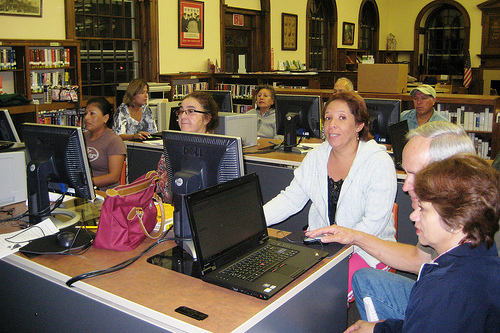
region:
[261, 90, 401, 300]
woman sitting at a table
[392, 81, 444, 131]
man sitting at a computer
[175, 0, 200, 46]
framed picture on wall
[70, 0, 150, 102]
large glass window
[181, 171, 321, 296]
black laptop on table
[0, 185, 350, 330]
long table with computers on it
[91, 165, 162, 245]
bright pink bag on table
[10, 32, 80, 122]
bookcase with many books in it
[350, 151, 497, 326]
older lady sitting at table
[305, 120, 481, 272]
older man next to lady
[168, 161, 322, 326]
the screen is off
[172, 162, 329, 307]
the computer is black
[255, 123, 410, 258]
the cloth is white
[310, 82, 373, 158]
the woman is smiling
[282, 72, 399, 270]
the woman is white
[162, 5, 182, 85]
the wall is yellow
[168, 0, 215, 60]
the picture is hanging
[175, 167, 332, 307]
the computer is off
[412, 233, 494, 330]
the shirt is dark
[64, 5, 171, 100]
the window is closed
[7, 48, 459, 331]
Computers at a library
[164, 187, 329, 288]
Black laptop computer on table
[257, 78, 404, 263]
Woman in white sitting in front of computer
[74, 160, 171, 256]
Pink purse on table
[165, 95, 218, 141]
Woman wearing glasses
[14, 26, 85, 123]
Book shelf against wall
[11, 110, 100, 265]
Back of a computer monitor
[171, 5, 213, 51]
Framed poster on library wall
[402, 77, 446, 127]
Man wearing baseball hat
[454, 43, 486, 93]
Flag in the back of a room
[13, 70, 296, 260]
women working on computers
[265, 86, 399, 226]
woman wearing a white hoodie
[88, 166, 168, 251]
pink handbag with leather trim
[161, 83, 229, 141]
woman wearing cat-eye glasses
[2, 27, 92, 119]
wood bookcase in a library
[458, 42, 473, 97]
american flag on a flag pole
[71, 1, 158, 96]
large window partially open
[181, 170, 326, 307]
black laptop computer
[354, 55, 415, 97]
cardboard box on top of bookcase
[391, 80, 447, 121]
man wearing baseball cap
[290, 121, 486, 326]
Man is using laptop computer.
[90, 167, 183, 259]
Pink canvas purse is sitting on desk.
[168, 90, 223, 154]
Woman is smiling at computer screen.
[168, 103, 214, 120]
Woman is wearing glasses.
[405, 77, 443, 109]
Man is wearing baseball cap.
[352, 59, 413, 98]
Cardboard box sitting on counter.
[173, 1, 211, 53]
Framed picture hanging on wall.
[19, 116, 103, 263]
Woman is using flat screen.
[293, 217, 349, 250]
Man is holding computer mouse.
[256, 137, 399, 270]
Woman is wearing white sweater.